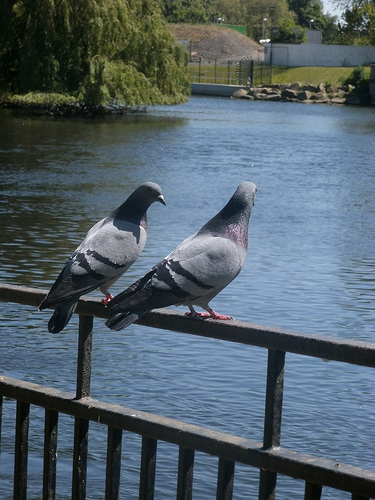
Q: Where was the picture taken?
A: It was taken at the lake.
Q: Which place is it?
A: It is a lake.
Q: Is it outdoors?
A: Yes, it is outdoors.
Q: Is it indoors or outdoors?
A: It is outdoors.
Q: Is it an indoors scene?
A: No, it is outdoors.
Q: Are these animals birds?
A: No, they are pigeons and birds.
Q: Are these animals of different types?
A: Yes, they are pigeons and birds.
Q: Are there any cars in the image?
A: No, there are no cars.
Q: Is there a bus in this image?
A: No, there are no buses.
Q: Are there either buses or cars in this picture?
A: No, there are no buses or cars.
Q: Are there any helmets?
A: No, there are no helmets.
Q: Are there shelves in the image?
A: No, there are no shelves.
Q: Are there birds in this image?
A: Yes, there is a bird.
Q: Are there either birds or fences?
A: Yes, there is a bird.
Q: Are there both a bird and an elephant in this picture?
A: No, there is a bird but no elephants.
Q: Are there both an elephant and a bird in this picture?
A: No, there is a bird but no elephants.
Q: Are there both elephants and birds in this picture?
A: No, there is a bird but no elephants.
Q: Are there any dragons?
A: No, there are no dragons.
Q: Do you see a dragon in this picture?
A: No, there are no dragons.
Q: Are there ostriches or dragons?
A: No, there are no dragons or ostriches.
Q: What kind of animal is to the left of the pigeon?
A: The animal is a bird.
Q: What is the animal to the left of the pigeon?
A: The animal is a bird.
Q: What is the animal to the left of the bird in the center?
A: The animal is a bird.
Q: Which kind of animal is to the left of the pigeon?
A: The animal is a bird.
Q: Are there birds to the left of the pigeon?
A: Yes, there is a bird to the left of the pigeon.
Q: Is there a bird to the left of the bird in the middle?
A: Yes, there is a bird to the left of the pigeon.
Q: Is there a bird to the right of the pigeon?
A: No, the bird is to the left of the pigeon.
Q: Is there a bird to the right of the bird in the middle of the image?
A: No, the bird is to the left of the pigeon.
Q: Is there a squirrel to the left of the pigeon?
A: No, there is a bird to the left of the pigeon.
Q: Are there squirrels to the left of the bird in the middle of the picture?
A: No, there is a bird to the left of the pigeon.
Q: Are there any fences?
A: Yes, there is a fence.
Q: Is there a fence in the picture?
A: Yes, there is a fence.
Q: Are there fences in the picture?
A: Yes, there is a fence.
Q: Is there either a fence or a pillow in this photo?
A: Yes, there is a fence.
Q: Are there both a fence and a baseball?
A: No, there is a fence but no baseballs.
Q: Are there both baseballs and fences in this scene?
A: No, there is a fence but no baseballs.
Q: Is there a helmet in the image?
A: No, there are no helmets.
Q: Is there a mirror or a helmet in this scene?
A: No, there are no helmets or mirrors.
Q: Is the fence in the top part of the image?
A: Yes, the fence is in the top of the image.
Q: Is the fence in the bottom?
A: No, the fence is in the top of the image.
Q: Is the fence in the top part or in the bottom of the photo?
A: The fence is in the top of the image.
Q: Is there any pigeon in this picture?
A: Yes, there is a pigeon.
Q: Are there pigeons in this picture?
A: Yes, there is a pigeon.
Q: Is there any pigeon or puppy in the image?
A: Yes, there is a pigeon.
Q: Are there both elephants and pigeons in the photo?
A: No, there is a pigeon but no elephants.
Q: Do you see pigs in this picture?
A: No, there are no pigs.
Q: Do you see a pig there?
A: No, there are no pigs.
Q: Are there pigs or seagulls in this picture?
A: No, there are no pigs or seagulls.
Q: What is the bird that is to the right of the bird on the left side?
A: The bird is a pigeon.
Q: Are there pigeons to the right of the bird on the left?
A: Yes, there is a pigeon to the right of the bird.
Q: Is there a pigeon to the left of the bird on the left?
A: No, the pigeon is to the right of the bird.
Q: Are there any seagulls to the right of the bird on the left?
A: No, there is a pigeon to the right of the bird.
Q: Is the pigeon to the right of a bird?
A: Yes, the pigeon is to the right of a bird.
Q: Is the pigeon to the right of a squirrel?
A: No, the pigeon is to the right of a bird.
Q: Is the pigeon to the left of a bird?
A: No, the pigeon is to the right of a bird.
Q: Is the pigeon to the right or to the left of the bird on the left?
A: The pigeon is to the right of the bird.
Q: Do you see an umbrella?
A: No, there are no umbrellas.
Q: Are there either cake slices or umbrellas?
A: No, there are no umbrellas or cake slices.